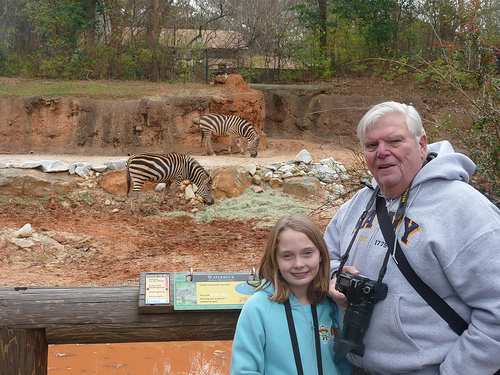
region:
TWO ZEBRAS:
[112, 104, 264, 209]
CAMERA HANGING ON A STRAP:
[329, 194, 401, 371]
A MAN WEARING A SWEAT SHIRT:
[323, 77, 493, 372]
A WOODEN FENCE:
[3, 283, 249, 371]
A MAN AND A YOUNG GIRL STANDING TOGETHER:
[223, 93, 498, 370]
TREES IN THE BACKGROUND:
[8, 47, 198, 82]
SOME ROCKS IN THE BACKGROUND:
[251, 148, 348, 200]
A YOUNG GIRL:
[226, 217, 367, 371]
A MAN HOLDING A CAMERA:
[319, 86, 496, 373]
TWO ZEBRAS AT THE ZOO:
[115, 91, 269, 215]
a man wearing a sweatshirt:
[320, 99, 498, 374]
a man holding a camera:
[323, 101, 498, 374]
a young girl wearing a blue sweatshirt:
[227, 213, 344, 373]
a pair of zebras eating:
[122, 108, 263, 209]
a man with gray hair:
[322, 99, 498, 373]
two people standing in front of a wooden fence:
[2, 101, 498, 373]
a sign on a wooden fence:
[0, 267, 256, 374]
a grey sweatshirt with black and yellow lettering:
[321, 137, 498, 374]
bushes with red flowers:
[419, 1, 499, 79]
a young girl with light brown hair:
[227, 212, 352, 373]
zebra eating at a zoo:
[127, 155, 215, 210]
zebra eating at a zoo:
[194, 111, 261, 161]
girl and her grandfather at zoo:
[227, 95, 482, 372]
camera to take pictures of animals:
[332, 251, 389, 363]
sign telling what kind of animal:
[134, 258, 278, 313]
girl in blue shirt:
[232, 206, 339, 373]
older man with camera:
[322, 89, 498, 371]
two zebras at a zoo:
[126, 96, 265, 220]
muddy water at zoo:
[43, 337, 230, 374]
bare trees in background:
[14, 8, 483, 84]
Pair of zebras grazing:
[112, 100, 262, 230]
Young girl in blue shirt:
[230, 208, 362, 370]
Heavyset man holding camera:
[330, 96, 497, 373]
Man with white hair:
[335, 96, 499, 373]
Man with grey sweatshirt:
[325, 94, 499, 371]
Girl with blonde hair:
[225, 210, 352, 370]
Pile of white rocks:
[240, 143, 351, 188]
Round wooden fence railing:
[8, 282, 255, 347]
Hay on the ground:
[203, 183, 316, 228]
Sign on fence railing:
[134, 260, 288, 312]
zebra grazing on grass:
[121, 150, 216, 207]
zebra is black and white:
[193, 112, 260, 162]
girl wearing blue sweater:
[228, 211, 346, 373]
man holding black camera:
[320, 99, 499, 374]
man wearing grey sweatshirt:
[322, 100, 499, 373]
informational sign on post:
[138, 265, 263, 310]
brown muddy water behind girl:
[44, 340, 240, 372]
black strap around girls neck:
[281, 298, 326, 373]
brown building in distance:
[119, 24, 308, 82]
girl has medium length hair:
[252, 212, 328, 304]